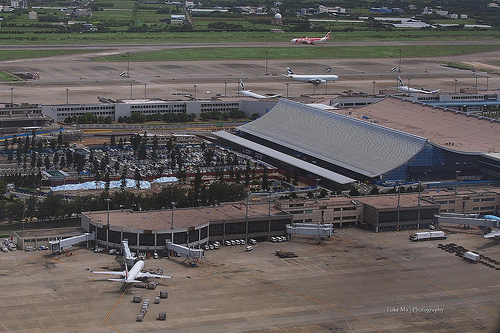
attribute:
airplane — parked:
[92, 252, 177, 290]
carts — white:
[200, 234, 287, 251]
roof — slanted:
[239, 84, 454, 179]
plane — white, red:
[292, 33, 336, 47]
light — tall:
[67, 87, 72, 107]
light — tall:
[9, 85, 15, 110]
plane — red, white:
[289, 30, 331, 45]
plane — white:
[236, 82, 268, 104]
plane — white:
[287, 28, 332, 45]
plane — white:
[285, 63, 342, 92]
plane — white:
[97, 253, 168, 300]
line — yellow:
[86, 289, 140, 321]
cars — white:
[270, 235, 277, 243]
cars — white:
[248, 236, 259, 246]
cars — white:
[245, 245, 253, 252]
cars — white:
[223, 239, 231, 246]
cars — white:
[211, 242, 220, 248]